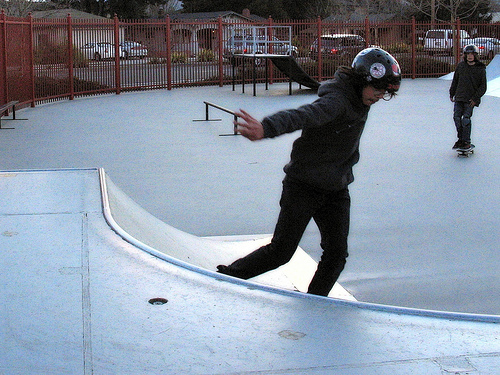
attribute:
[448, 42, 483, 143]
boy — teen, young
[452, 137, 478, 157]
skateboard — wooden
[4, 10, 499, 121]
fence — tall, maroon, rail, red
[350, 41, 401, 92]
helmet — black colored, black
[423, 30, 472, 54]
van — white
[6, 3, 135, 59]
house — tan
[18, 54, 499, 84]
street — suburban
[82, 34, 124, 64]
sedan — parked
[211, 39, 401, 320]
boy — skateboarding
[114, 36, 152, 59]
car — parked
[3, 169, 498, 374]
ramp — lifted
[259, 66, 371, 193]
shirt — gray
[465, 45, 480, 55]
helmet — black, black colored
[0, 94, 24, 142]
bench — iron